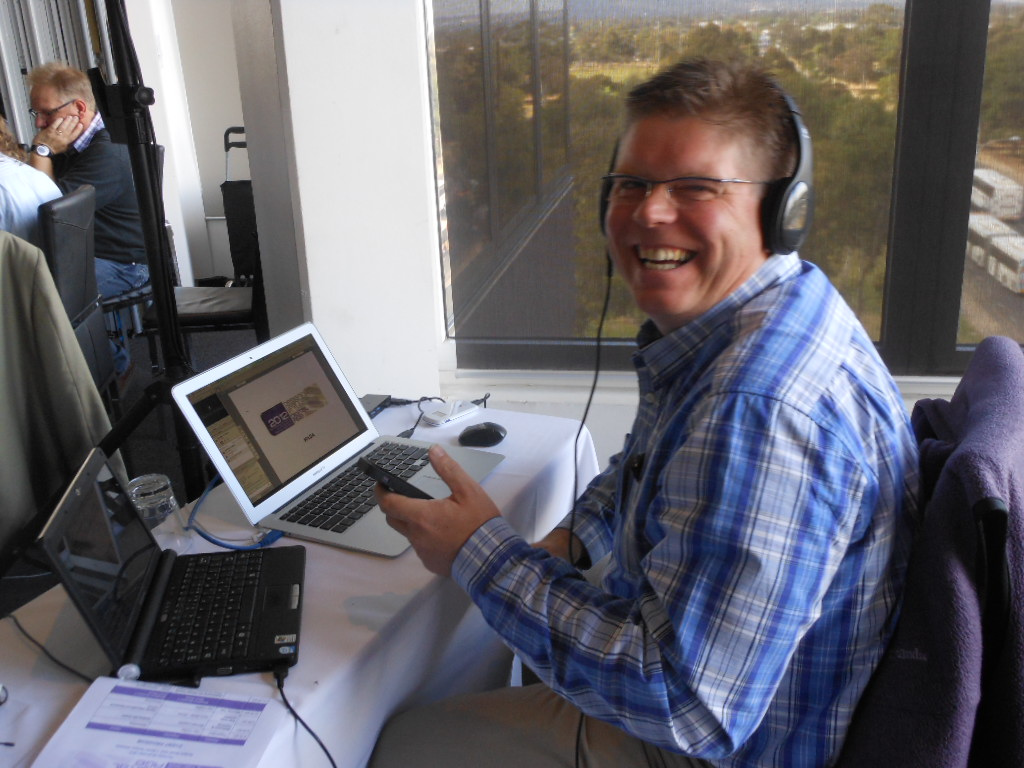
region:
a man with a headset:
[596, 53, 818, 328]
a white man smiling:
[593, 89, 750, 336]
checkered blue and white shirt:
[392, 332, 920, 744]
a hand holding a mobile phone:
[344, 442, 521, 598]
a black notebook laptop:
[38, 439, 317, 695]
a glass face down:
[125, 470, 205, 570]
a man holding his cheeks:
[21, 59, 110, 181]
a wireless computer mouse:
[452, 417, 519, 456]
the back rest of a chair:
[29, 180, 137, 468]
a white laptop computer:
[174, 313, 488, 557]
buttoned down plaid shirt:
[448, 253, 917, 766]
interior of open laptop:
[38, 445, 307, 680]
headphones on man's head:
[598, 53, 815, 323]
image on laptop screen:
[174, 322, 374, 519]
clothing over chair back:
[844, 332, 1019, 765]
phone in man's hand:
[359, 450, 497, 597]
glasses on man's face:
[606, 64, 796, 324]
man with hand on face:
[22, 63, 92, 174]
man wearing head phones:
[580, 62, 824, 256]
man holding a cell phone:
[355, 442, 439, 509]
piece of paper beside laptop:
[25, 663, 301, 765]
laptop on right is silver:
[149, 314, 522, 578]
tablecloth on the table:
[0, 359, 602, 765]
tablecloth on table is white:
[3, 391, 613, 761]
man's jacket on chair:
[820, 296, 1020, 765]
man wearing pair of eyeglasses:
[591, 163, 794, 228]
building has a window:
[433, 3, 893, 351]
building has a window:
[430, 0, 491, 275]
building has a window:
[535, 5, 571, 193]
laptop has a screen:
[167, 322, 368, 529]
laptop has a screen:
[42, 461, 159, 670]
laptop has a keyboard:
[145, 542, 301, 676]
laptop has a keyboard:
[276, 436, 495, 560]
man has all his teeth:
[624, 239, 697, 275]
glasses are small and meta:
[601, 172, 773, 205]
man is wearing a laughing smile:
[382, 80, 930, 761]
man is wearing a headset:
[381, 57, 922, 760]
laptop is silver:
[173, 322, 502, 566]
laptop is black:
[43, 430, 320, 675]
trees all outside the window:
[544, 7, 1022, 359]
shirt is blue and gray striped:
[446, 272, 912, 766]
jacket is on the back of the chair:
[852, 339, 1021, 766]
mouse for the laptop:
[446, 410, 510, 453]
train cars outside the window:
[961, 151, 1022, 294]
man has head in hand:
[27, 60, 152, 304]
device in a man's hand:
[354, 451, 446, 510]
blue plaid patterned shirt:
[445, 234, 920, 766]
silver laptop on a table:
[163, 310, 512, 560]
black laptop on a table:
[34, 436, 328, 683]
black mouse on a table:
[454, 416, 513, 451]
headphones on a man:
[588, 50, 826, 270]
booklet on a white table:
[12, 658, 282, 766]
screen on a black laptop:
[40, 452, 176, 661]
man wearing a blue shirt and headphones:
[406, 51, 907, 764]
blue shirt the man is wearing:
[456, 294, 893, 763]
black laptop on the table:
[43, 439, 306, 681]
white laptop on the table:
[169, 314, 512, 559]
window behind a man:
[418, 3, 1022, 384]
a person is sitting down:
[388, 48, 913, 766]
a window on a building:
[421, 10, 890, 369]